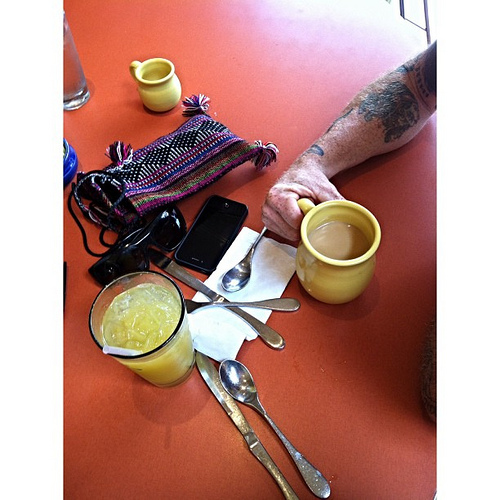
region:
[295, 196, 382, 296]
a yellow coffee mug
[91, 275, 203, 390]
a glass on the table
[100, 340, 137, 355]
a straw in the glass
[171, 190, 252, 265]
a black cell phone on the table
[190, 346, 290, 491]
a knife on the table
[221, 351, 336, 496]
a spoon on the table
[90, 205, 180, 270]
sunglasses on the table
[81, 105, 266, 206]
a bag on the table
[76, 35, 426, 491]
a red table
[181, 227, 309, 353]
a white napkin on the table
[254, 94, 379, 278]
the hand of a man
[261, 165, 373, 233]
the fingers of a man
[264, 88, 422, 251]
the arm of a man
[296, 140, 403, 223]
the thumb of a man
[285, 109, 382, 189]
the wrist of a man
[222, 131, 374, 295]
a man holding a cup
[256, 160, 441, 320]
a cup on a table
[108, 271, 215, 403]
a glass on a table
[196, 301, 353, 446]
a spoon on a table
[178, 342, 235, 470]
a knife on a table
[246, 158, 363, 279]
the hand of a man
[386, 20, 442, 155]
the elbow of a man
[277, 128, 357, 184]
the wrist of a man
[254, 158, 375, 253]
the hand of a man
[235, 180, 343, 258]
the fingers of a man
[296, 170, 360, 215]
the thumb of a man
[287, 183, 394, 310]
a cup on a table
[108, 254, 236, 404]
the glass on a table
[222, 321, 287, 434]
a spoon on a table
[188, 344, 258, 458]
a knife on a table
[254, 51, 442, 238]
Several tattoos on a persons arm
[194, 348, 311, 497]
A silver butter knife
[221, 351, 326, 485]
A silver spoon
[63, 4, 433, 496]
A red table top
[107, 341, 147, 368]
A white straw in a cup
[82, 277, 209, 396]
A large clear glass cup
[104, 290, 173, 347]
Ice floating on top of a drink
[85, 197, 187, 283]
A pair of black sunglasses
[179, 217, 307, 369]
A white napkin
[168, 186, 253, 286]
A black iphone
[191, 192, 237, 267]
a phone sitting on a table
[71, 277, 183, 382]
a straw sticking out of a glass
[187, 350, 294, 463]
knife and spoon laying on a table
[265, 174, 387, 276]
someone holding a coffee cup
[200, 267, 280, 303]
a spoon on top of a napkin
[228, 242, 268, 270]
a napking on top of a table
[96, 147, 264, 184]
a bag sitting on top of a table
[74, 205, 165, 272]
sunglasses sitting on top of a table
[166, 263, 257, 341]
a spoon crossing a knife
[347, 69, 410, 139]
a tattoo imprinted on a arm